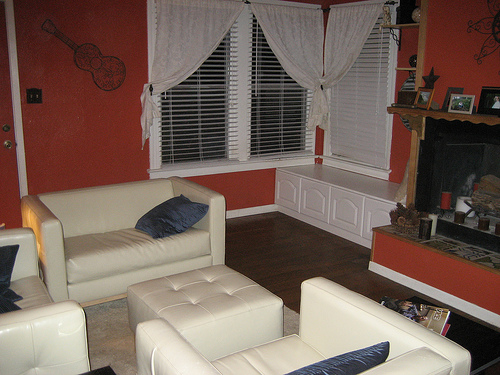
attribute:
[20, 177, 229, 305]
love seat — leather, white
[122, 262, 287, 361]
ottoman — white, leather, square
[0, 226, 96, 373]
chair — white, leather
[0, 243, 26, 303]
pillow — blue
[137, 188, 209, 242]
pillow — blue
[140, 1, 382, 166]
curtains — white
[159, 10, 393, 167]
blinds — white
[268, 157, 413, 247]
window seat — white, box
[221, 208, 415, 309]
floors — dark, wooden, dark brown, wood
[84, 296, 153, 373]
carpet — cream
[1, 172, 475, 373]
furniture — white, upholstered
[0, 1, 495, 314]
walls — red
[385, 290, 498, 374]
table — black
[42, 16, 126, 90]
decoration — guitar, metal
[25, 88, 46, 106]
light switch — black